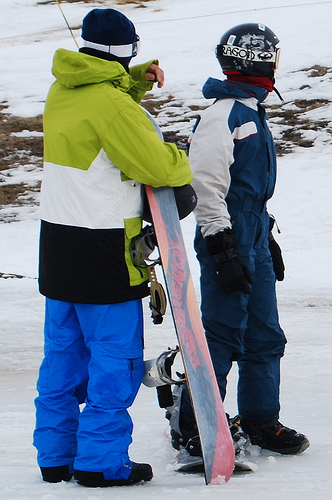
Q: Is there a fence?
A: No, there are no fences.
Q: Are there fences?
A: No, there are no fences.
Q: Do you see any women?
A: No, there are no women.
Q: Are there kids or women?
A: No, there are no women or kids.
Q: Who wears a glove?
A: The man wears a glove.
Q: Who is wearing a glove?
A: The man is wearing a glove.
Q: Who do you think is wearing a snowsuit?
A: The man is wearing a snowsuit.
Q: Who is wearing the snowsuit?
A: The man is wearing a snowsuit.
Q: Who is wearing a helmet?
A: The man is wearing a helmet.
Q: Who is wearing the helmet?
A: The man is wearing a helmet.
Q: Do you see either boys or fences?
A: No, there are no fences or boys.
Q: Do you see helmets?
A: Yes, there is a helmet.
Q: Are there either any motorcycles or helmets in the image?
A: Yes, there is a helmet.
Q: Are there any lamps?
A: No, there are no lamps.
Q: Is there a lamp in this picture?
A: No, there are no lamps.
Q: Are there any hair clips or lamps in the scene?
A: No, there are no lamps or hair clips.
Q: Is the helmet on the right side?
A: Yes, the helmet is on the right of the image.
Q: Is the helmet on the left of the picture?
A: No, the helmet is on the right of the image.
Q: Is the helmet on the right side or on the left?
A: The helmet is on the right of the image.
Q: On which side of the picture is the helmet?
A: The helmet is on the right of the image.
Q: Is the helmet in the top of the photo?
A: Yes, the helmet is in the top of the image.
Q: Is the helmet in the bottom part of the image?
A: No, the helmet is in the top of the image.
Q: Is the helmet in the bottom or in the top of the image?
A: The helmet is in the top of the image.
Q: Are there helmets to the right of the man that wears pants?
A: Yes, there is a helmet to the right of the man.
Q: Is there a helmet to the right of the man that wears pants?
A: Yes, there is a helmet to the right of the man.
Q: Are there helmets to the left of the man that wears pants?
A: No, the helmet is to the right of the man.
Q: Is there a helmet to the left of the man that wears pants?
A: No, the helmet is to the right of the man.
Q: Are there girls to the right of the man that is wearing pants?
A: No, there is a helmet to the right of the man.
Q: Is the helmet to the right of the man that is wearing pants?
A: Yes, the helmet is to the right of the man.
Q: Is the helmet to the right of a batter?
A: No, the helmet is to the right of the man.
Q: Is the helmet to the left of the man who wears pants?
A: No, the helmet is to the right of the man.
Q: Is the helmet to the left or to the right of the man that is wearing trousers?
A: The helmet is to the right of the man.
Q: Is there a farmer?
A: No, there are no farmers.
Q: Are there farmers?
A: No, there are no farmers.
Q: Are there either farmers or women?
A: No, there are no farmers or women.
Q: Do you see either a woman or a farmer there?
A: No, there are no farmers or women.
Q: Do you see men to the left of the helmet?
A: Yes, there is a man to the left of the helmet.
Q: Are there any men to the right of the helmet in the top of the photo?
A: No, the man is to the left of the helmet.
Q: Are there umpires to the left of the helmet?
A: No, there is a man to the left of the helmet.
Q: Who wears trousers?
A: The man wears trousers.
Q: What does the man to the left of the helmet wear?
A: The man wears pants.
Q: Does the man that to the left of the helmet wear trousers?
A: Yes, the man wears trousers.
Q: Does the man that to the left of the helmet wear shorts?
A: No, the man wears trousers.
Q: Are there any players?
A: No, there are no players.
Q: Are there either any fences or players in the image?
A: No, there are no players or fences.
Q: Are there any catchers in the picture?
A: No, there are no catchers.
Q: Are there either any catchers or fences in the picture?
A: No, there are no catchers or fences.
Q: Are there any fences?
A: No, there are no fences.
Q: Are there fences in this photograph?
A: No, there are no fences.